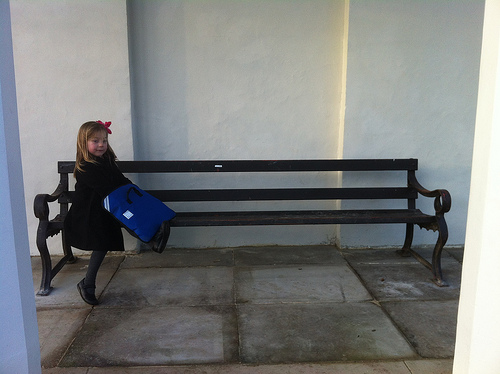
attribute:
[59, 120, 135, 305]
girl — sitting, little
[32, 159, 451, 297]
bench — long, mettalic, black, metal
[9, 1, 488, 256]
wall — white, smooth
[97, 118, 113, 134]
ribbon — red, pink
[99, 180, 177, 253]
bag — blue, black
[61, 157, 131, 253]
jacket — black, long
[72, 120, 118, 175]
hair — brown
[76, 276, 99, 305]
shoe — black, nice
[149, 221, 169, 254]
shoe — black, nice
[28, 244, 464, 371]
floor — brown, dark grey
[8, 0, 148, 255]
side — thick, white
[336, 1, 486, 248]
side — thick, white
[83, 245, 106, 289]
tights — grey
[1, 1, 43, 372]
wall — white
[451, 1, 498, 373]
wall — white